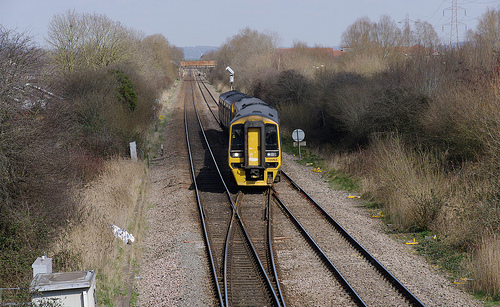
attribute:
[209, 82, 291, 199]
train — yellow, black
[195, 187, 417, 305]
tracks — multiple, railroad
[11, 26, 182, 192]
trees — dead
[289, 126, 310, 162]
sign — back side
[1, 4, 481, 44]
gray sky — polluted, cloudy, cloudless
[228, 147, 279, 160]
lights — turned off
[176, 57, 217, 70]
bridge — yellow, rusty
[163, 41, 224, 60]
mountain range — large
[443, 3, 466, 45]
pole — tall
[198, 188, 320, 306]
track — switch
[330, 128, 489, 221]
shrubs — brown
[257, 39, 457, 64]
houses — red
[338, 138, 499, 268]
grass — dead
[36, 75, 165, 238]
underbrush — thick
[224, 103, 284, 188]
car — train